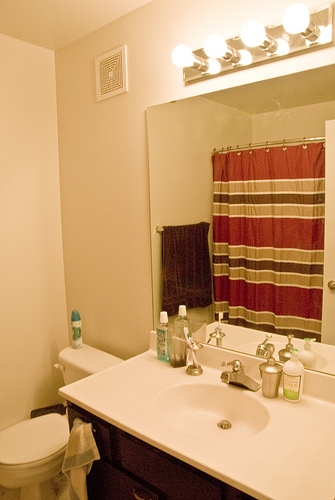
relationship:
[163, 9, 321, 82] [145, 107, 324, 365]
fixture over mirror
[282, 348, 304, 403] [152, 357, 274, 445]
bottle on sink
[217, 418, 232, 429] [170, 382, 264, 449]
drain in sink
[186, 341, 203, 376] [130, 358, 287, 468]
holder on sink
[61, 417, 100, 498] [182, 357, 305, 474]
towel in front of sink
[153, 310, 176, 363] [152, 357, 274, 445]
bottle on sink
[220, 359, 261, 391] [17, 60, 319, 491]
faucet in bathroom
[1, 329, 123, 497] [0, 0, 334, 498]
toilet in bathroom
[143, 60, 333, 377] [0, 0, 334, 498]
mirror in bathroom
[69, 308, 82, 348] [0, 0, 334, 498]
can in bathroom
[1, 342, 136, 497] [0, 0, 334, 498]
toilet in bathroom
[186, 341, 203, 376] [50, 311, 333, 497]
holder on counter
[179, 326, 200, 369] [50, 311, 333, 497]
toothbrush on counter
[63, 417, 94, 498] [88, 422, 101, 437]
towel on handle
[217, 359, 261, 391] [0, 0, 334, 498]
faucet in bathroom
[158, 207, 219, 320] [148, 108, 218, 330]
towel on wall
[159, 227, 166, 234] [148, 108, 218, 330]
rack on wall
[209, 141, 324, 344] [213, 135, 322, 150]
shower curtain hanging on rod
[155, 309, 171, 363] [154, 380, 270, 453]
mouth wash on sink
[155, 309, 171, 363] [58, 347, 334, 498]
mouth wash on counter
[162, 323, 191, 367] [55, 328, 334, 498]
cup on counter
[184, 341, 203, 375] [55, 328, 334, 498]
holder on counter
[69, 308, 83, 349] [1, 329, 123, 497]
aerosol on toilet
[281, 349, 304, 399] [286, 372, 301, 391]
bottle of lotion